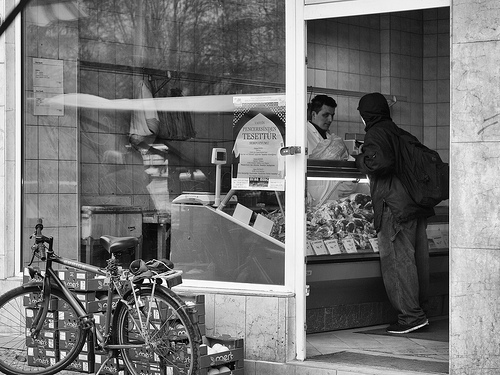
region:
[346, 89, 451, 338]
the man at the counter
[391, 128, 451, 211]
the black backpack on the man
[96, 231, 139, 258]
the black seat on the bike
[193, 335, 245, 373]
the crates on the ground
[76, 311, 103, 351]
the pedal of the bike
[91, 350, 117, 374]
the kickstand on the ground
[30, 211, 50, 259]
the handle bars of the bike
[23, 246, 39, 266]
the brake of the bike handle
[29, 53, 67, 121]
the paper on the wall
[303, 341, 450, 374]
the rug in the doorway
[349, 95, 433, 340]
A person in the store.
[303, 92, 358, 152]
A man behind the counter.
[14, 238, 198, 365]
A bike in front of the store.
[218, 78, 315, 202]
A sign in the store window.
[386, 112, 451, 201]
The person is carrying a backpack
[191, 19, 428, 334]
The store sells food.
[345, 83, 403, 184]
The person is wearing a hoodie.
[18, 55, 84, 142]
Sign posted inside the store.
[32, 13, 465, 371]
The photo is black and white.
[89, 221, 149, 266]
The seat of the bicycle.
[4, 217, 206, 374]
a bike by the window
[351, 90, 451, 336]
a person is leaning over the display case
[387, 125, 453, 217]
the person is wearing a backpack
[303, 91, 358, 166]
a man behind the display case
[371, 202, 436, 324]
the person is wearing jeans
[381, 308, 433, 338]
the person is wearing shoes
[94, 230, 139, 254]
the bike has a seat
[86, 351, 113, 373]
the bike has a kickstand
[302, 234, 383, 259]
small signs on the display case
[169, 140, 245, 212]
a scale by the display case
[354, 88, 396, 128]
head of a person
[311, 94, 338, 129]
head of a person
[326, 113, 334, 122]
nose of a person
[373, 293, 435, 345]
leg of a person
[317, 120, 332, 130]
mouth of a person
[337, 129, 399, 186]
arm of a person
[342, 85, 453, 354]
person wearing back pack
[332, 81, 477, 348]
person wearing pair of jeans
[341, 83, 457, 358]
person wearing a pair of sneakers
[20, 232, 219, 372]
bike on a street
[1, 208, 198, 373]
bicycle parked in front of a store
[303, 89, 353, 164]
man standing behind a counter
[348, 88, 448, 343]
man with a back pack looking over the counter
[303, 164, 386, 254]
glass counter with food items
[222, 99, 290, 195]
sign in the store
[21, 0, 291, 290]
large glass window on the store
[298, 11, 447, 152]
tile on the wall of the store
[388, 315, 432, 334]
black and white shoes on the man's feet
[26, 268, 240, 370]
crates on the ground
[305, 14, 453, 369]
open doorway to the store